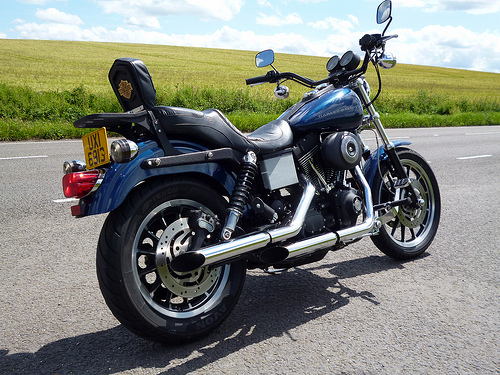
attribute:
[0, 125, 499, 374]
road — edgy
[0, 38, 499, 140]
grass — part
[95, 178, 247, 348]
wheel — part, edged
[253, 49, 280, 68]
mirror — part, rear, reflective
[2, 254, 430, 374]
shadow — part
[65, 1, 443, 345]
motorcycle — parked, blue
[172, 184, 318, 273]
pipe — chrome, silver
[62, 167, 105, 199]
light — red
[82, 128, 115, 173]
plate — yellow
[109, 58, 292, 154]
seat — leather, black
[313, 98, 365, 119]
logo — black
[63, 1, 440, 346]
bike — blue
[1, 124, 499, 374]
street — grey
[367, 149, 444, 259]
tire — black